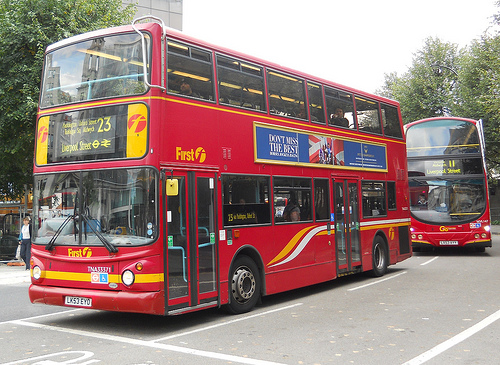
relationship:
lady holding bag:
[11, 210, 39, 272] [10, 240, 24, 262]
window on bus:
[307, 83, 334, 121] [57, 35, 408, 292]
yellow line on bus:
[32, 262, 158, 292] [31, 20, 416, 314]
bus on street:
[31, 20, 416, 314] [3, 229, 496, 359]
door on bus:
[159, 164, 220, 313] [31, 20, 416, 314]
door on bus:
[323, 167, 387, 297] [49, 12, 448, 317]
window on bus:
[353, 94, 383, 134] [31, 20, 416, 314]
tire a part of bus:
[226, 253, 263, 314] [31, 20, 416, 314]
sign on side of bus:
[242, 114, 392, 175] [31, 20, 416, 314]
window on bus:
[157, 35, 217, 107] [31, 20, 416, 314]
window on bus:
[265, 67, 310, 124] [31, 20, 416, 314]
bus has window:
[31, 20, 416, 314] [163, 32, 217, 104]